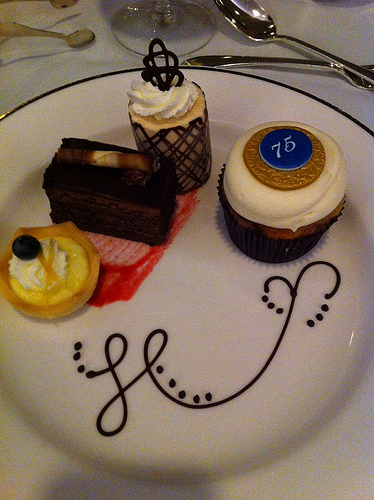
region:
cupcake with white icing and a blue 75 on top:
[218, 120, 347, 265]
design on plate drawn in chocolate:
[72, 259, 342, 446]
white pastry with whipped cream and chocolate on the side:
[128, 35, 210, 198]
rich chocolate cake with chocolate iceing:
[36, 136, 177, 244]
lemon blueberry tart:
[0, 217, 99, 316]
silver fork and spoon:
[185, 1, 373, 90]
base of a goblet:
[112, 0, 213, 57]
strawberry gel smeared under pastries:
[79, 194, 196, 307]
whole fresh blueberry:
[8, 234, 43, 262]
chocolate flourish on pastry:
[139, 35, 181, 90]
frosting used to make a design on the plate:
[141, 317, 206, 402]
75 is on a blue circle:
[269, 121, 301, 170]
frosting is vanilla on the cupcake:
[259, 195, 298, 228]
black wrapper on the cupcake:
[260, 232, 292, 258]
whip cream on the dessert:
[164, 94, 175, 112]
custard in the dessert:
[65, 253, 96, 282]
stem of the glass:
[135, 15, 189, 41]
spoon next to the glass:
[257, 9, 291, 44]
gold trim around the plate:
[271, 70, 298, 96]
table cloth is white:
[21, 41, 60, 95]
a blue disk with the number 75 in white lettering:
[257, 126, 316, 171]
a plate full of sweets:
[4, 63, 373, 498]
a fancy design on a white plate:
[68, 257, 341, 439]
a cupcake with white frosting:
[215, 118, 351, 265]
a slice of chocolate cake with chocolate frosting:
[39, 134, 180, 246]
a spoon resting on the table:
[214, 0, 371, 87]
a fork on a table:
[183, 53, 373, 87]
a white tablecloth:
[2, 0, 372, 130]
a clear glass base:
[104, 0, 218, 57]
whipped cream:
[126, 73, 200, 119]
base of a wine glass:
[108, 0, 215, 58]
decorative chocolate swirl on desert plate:
[71, 258, 341, 435]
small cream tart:
[0, 217, 103, 322]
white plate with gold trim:
[0, 62, 372, 497]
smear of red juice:
[65, 187, 199, 306]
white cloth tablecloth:
[0, 0, 373, 134]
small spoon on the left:
[0, 17, 95, 49]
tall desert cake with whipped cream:
[127, 34, 213, 192]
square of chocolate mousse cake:
[41, 135, 177, 246]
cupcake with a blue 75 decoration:
[213, 119, 350, 263]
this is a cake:
[212, 119, 352, 271]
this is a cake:
[0, 216, 108, 320]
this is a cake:
[32, 133, 178, 244]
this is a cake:
[125, 39, 229, 192]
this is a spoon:
[185, 41, 373, 91]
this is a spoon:
[219, 2, 371, 93]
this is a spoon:
[6, 20, 110, 54]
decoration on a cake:
[14, 232, 43, 260]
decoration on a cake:
[244, 128, 317, 187]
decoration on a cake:
[127, 33, 185, 94]